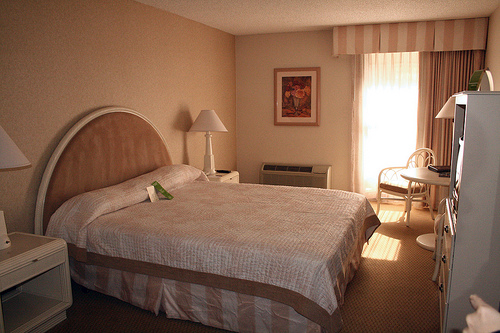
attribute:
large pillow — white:
[68, 163, 199, 217]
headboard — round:
[39, 85, 184, 195]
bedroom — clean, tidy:
[41, 2, 481, 319]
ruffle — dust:
[266, 60, 331, 133]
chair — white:
[376, 146, 437, 223]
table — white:
[400, 169, 450, 228]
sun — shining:
[356, 80, 421, 264]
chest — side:
[0, 226, 76, 330]